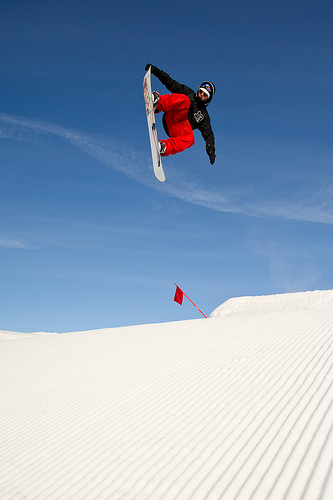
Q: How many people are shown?
A: 1.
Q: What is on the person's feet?
A: Snowboard.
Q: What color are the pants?
A: Red.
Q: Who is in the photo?
A: A snowboarder.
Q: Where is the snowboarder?
A: In the air.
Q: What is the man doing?
A: Snowboarding.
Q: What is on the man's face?
A: Sunglasses.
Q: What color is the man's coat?
A: Black.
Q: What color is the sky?
A: Blue.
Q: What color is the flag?
A: Red.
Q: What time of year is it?
A: Winter.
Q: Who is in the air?
A: Snowboarder.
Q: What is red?
A: Snowboarder's pants.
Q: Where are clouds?
A: In the sky.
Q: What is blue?
A: Sky.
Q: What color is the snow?
A: White.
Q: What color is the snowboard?
A: White.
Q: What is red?
A: Flag.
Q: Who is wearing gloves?
A: The snowboarder.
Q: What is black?
A: Jacket.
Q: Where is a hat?
A: On man's head.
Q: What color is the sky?
A: Blue.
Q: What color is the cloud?
A: White.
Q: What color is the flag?
A: Red.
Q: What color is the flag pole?
A: Red.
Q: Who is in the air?
A: Snowboarder.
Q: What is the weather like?
A: Sunny and cold.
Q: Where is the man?
A: In the air.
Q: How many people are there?
A: One.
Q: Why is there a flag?
A: Safety.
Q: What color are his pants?
A: Red.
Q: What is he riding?
A: Snowboard.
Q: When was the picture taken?
A: During the daytime.